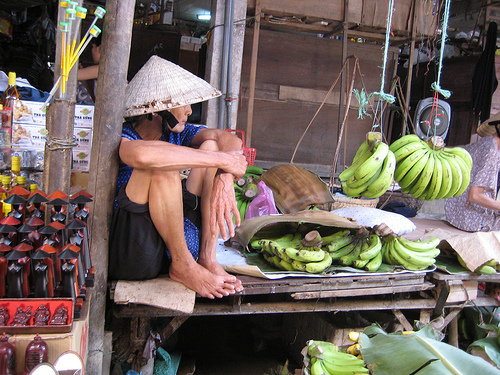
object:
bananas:
[366, 149, 397, 195]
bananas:
[353, 141, 390, 182]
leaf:
[435, 256, 470, 276]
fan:
[412, 97, 451, 142]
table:
[106, 272, 436, 318]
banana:
[321, 359, 372, 375]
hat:
[123, 52, 224, 119]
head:
[123, 51, 222, 134]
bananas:
[443, 146, 473, 171]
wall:
[243, 18, 382, 165]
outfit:
[105, 117, 209, 281]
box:
[0, 186, 94, 375]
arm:
[466, 149, 500, 212]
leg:
[477, 211, 500, 232]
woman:
[441, 119, 500, 234]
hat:
[113, 51, 230, 121]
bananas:
[295, 248, 328, 263]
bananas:
[396, 234, 442, 252]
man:
[107, 53, 248, 302]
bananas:
[424, 152, 444, 201]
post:
[77, 0, 134, 375]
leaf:
[355, 321, 500, 375]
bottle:
[2, 70, 22, 107]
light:
[187, 9, 213, 23]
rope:
[42, 134, 76, 154]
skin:
[149, 152, 205, 168]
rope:
[350, 12, 396, 124]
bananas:
[357, 233, 382, 261]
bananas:
[387, 134, 421, 153]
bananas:
[273, 245, 297, 261]